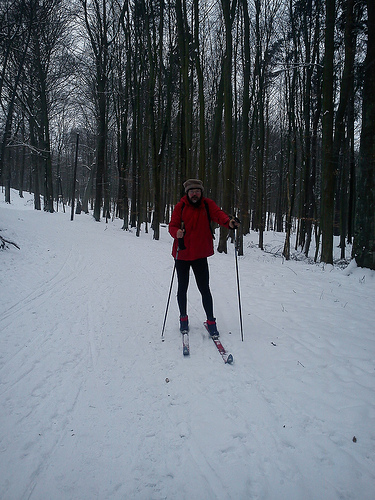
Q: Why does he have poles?
A: Balance.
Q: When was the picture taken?
A: Daytime.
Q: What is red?
A: Coat.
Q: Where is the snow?
A: On the ground.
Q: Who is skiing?
A: Man.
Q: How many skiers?
A: One.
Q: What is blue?
A: Sky.